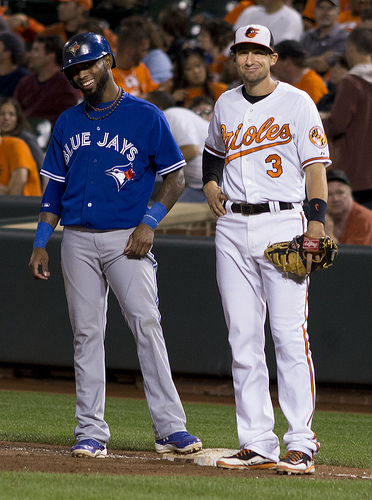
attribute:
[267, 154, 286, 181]
3 — orange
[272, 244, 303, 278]
mitt — brown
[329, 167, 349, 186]
hat — black, white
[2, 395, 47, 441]
grass — green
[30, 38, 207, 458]
ballplayer — smiling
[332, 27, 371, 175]
man — standing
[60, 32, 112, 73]
helmet — blue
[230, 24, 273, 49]
hat — white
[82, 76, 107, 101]
beard — black